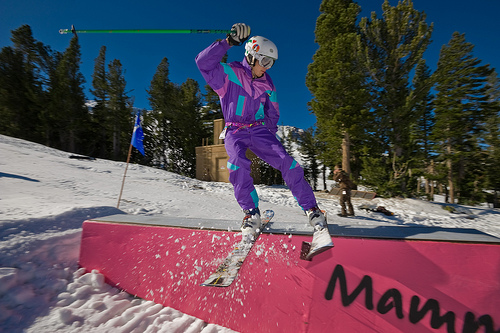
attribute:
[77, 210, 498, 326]
ramp — to ski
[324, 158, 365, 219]
person — standing